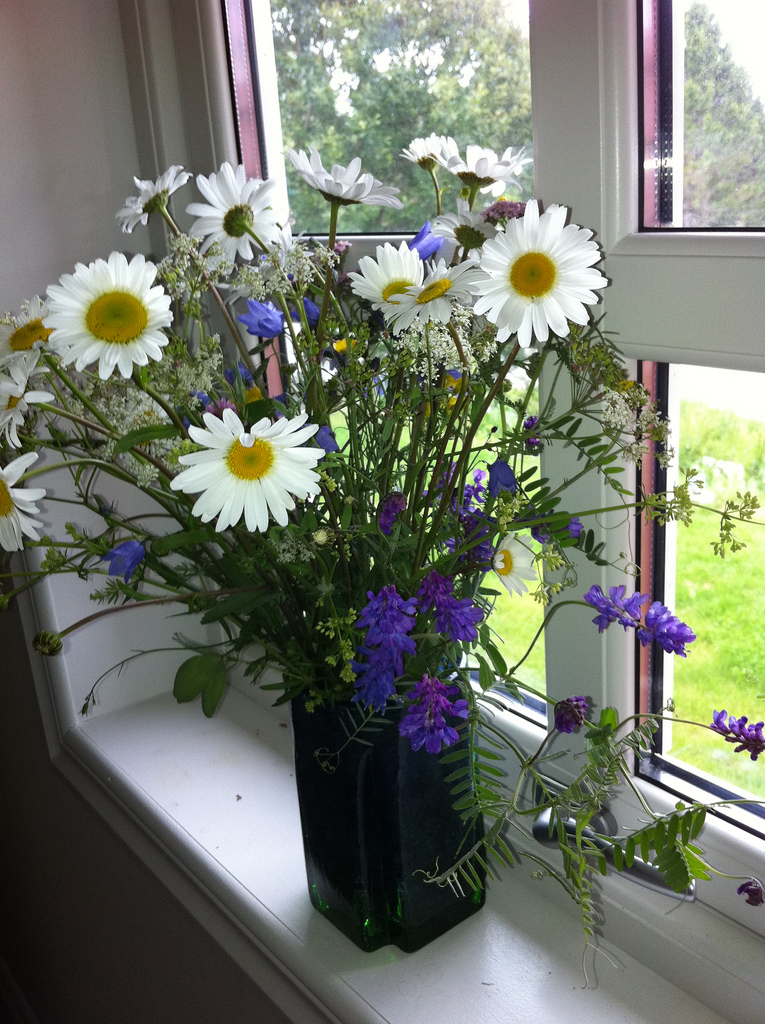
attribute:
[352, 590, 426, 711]
flower — purple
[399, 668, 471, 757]
flower — purple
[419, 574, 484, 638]
flower — purple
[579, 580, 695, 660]
flower — purple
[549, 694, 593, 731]
flower — purple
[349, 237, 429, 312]
flower — white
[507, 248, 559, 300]
flower — yellow